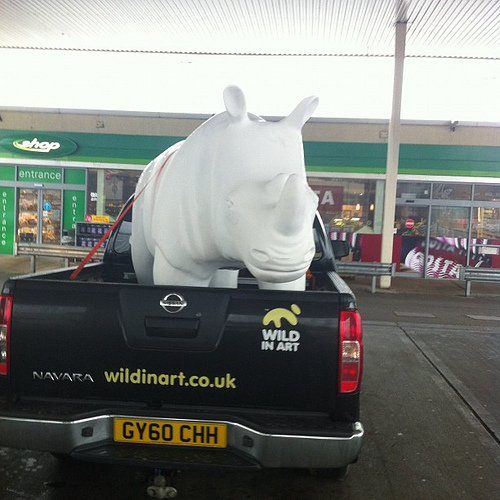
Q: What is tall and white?
A: The metal post.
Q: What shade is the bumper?
A: Silver.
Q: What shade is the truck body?
A: Black.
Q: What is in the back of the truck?
A: White rhino.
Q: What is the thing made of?
A: Ice.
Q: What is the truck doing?
A: It's parked.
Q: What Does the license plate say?
A: GY60 CHH.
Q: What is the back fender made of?
A: Metal.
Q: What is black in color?
A: The truck.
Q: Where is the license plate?
A: On the back of the truck.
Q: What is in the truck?
A: White rhino.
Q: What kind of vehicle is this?
A: Pick up.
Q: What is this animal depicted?
A: Rhino.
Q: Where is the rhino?
A: Back of a truck.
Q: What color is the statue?
A: White.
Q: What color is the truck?
A: Black.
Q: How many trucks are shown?
A: One.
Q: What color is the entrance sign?
A: Green.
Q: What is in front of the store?
A: Guard rails.